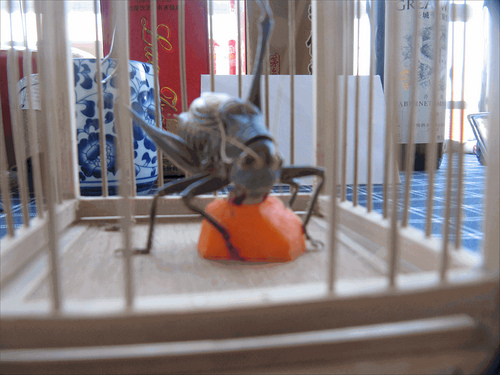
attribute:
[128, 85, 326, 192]
insect — gray, black, long legged, caged, multi legged, eating, eating orange item, small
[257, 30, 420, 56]
cage — white, in room, metal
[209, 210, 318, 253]
carrot — orange, fruit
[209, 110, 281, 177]
antenna — white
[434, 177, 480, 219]
tile — blue, square, white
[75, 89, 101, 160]
mug — blue, porcelain, white, patterned, on table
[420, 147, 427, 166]
wine bottle — on table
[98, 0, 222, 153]
box — red, gold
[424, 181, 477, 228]
floor — blue, white, tiled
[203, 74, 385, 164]
white board — large, on table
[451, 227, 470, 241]
tablecloth — blue, checkered, white